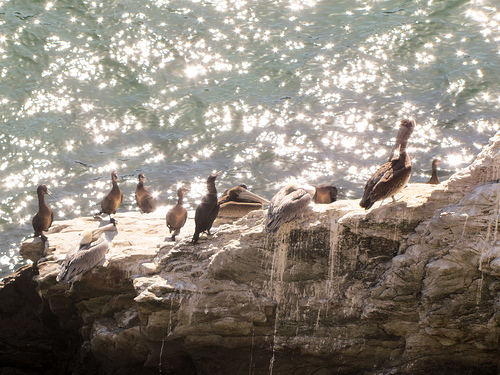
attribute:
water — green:
[6, 3, 497, 189]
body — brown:
[360, 161, 412, 201]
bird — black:
[187, 173, 224, 248]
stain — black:
[285, 227, 330, 279]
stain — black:
[347, 231, 405, 263]